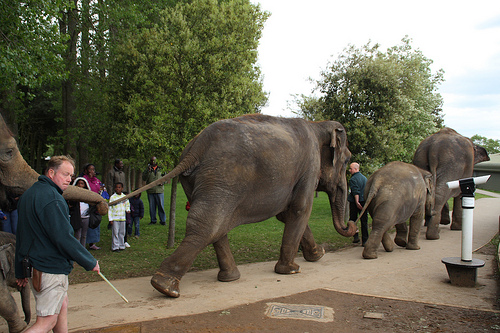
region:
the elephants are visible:
[168, 126, 341, 323]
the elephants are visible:
[221, 139, 329, 295]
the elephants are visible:
[264, 171, 306, 263]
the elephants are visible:
[264, 176, 342, 325]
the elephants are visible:
[208, 60, 318, 222]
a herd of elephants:
[13, 41, 491, 318]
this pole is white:
[413, 150, 498, 313]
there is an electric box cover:
[239, 264, 351, 331]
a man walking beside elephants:
[19, 130, 176, 319]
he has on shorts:
[19, 129, 139, 319]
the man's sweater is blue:
[14, 123, 168, 311]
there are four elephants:
[22, 103, 476, 316]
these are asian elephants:
[26, 49, 494, 310]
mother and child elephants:
[288, 85, 388, 262]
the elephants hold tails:
[211, 85, 493, 310]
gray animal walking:
[181, 93, 360, 283]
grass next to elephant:
[238, 219, 282, 259]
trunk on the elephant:
[319, 191, 361, 233]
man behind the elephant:
[18, 140, 113, 255]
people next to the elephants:
[81, 148, 153, 223]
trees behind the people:
[101, 76, 196, 119]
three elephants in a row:
[249, 112, 493, 235]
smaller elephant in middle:
[368, 155, 438, 246]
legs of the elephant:
[151, 218, 322, 305]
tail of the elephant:
[346, 183, 384, 230]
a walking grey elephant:
[114, 103, 353, 295]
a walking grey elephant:
[0, 85, 108, 318]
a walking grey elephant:
[361, 157, 432, 254]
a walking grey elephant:
[413, 124, 490, 228]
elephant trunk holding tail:
[0, 120, 187, 310]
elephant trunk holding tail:
[331, 172, 374, 239]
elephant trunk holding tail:
[426, 167, 443, 217]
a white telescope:
[441, 165, 492, 264]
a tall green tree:
[106, 0, 263, 251]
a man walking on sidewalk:
[16, 154, 103, 327]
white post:
[422, 171, 490, 253]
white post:
[405, 137, 479, 284]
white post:
[447, 170, 489, 311]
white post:
[442, 181, 472, 315]